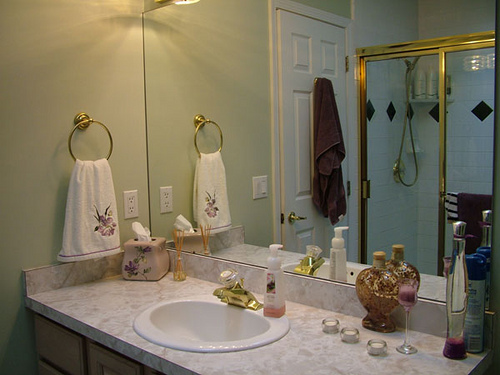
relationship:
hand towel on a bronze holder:
[56, 156, 126, 264] [66, 110, 114, 159]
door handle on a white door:
[288, 210, 308, 229] [268, 2, 380, 261]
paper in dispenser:
[130, 218, 158, 247] [113, 235, 174, 282]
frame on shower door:
[348, 41, 388, 262] [348, 28, 498, 279]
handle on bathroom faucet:
[215, 266, 245, 289] [209, 265, 262, 313]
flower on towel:
[91, 201, 118, 237] [56, 155, 125, 261]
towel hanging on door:
[308, 71, 354, 222] [262, 3, 365, 265]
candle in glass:
[399, 282, 418, 301] [393, 276, 424, 362]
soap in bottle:
[264, 302, 289, 317] [259, 239, 293, 324]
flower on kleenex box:
[124, 253, 147, 282] [121, 220, 170, 284]